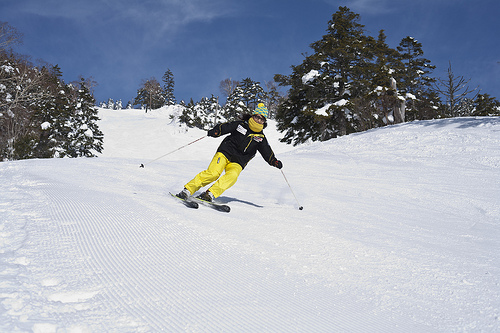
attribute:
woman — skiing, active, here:
[212, 93, 281, 202]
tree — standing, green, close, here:
[306, 8, 413, 104]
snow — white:
[309, 103, 342, 125]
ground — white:
[66, 189, 165, 294]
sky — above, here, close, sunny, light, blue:
[158, 9, 270, 79]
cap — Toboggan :
[248, 97, 269, 127]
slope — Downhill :
[0, 98, 493, 325]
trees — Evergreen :
[0, 29, 499, 173]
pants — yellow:
[180, 156, 249, 206]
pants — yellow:
[187, 156, 247, 206]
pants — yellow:
[184, 151, 243, 201]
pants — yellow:
[178, 149, 245, 201]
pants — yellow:
[189, 150, 241, 201]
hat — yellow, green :
[245, 94, 275, 132]